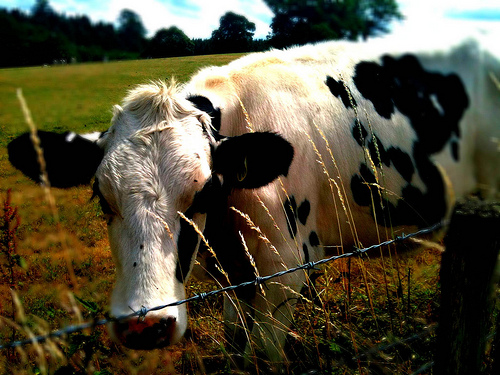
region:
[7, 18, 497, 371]
black and white cow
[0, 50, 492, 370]
cow standing in field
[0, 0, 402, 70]
trees behind field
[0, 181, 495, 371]
fence in front of cow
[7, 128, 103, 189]
ear on cow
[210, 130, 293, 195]
ear on cow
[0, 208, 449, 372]
barbed wire on fence post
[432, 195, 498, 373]
fence post in front of cow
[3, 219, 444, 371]
barbed wire in front of cow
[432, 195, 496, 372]
barbed wire behind fence post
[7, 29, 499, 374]
black and white cow standing in grass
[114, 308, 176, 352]
nose on the cow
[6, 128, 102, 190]
right ear on cow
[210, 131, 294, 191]
left ear on the cow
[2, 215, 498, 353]
barbed wire fence by cow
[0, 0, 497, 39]
blue cloudy sky in background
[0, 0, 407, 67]
group of trees at field's edge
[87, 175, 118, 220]
right eye of cow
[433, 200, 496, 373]
wooden fence post by cow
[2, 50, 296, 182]
green field behind cow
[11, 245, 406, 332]
barbed wire fence in field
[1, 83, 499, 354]
cow standing by fence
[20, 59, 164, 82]
pasture behind cow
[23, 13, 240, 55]
trees around edge of pasture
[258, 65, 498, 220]
cow has black and white spots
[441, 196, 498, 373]
wooden post holding fence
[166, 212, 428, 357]
weeds along fence line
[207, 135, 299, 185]
cow's ear is black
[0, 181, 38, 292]
red plant growing in pasture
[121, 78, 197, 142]
tuft of fur on cow's head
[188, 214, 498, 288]
a length of barbed wire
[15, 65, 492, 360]
a black and white cow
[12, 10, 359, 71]
a line of trees on the horizon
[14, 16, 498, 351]
a cow with black spots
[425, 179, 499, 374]
a wooden fence post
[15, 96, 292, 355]
the head of a black and white cow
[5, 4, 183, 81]
a green field flanked by trees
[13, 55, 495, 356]
a cow behind a barbed wire fence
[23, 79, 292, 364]
a cow with a pink nose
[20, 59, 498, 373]
a cow standing in a field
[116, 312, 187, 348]
pink nose on a cow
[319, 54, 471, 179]
black spots on the cow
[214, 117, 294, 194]
a black furry ear on a head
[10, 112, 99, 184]
a black furry ear on a head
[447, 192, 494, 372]
a wooden post next to the cow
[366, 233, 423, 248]
a barbed wire fence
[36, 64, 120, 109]
green grass on a small hill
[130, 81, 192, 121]
a tuft of white hair on a head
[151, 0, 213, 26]
white clouds in the sky